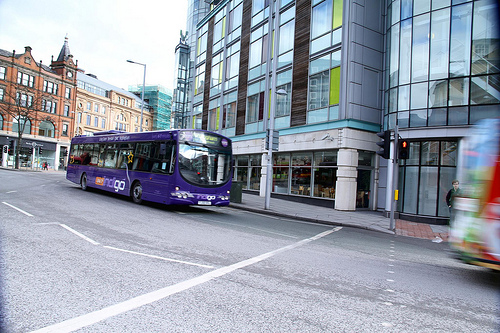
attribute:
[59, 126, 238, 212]
bus — purple, fast, white, transit, public, large, shiny, popular, helpful, moving, inexpensive, reliable, hot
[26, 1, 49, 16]
sky — gray, hazy, blue, cloudy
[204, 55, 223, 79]
window — gray, shiny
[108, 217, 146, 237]
road — gray, smooth